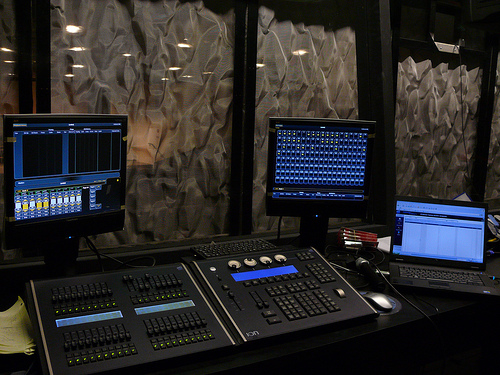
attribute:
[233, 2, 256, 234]
jamb — black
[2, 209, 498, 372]
desk — black, long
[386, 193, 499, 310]
laptop — running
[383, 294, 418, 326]
desk — wooden, black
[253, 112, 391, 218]
screen — blue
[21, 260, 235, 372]
board — mixing, black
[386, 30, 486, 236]
window — large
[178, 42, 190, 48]
reflection — light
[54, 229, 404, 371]
board. — sound board, advanced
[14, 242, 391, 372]
equipment — ready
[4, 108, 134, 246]
screen — blue black and yellow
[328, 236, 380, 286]
microphone — black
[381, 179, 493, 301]
laptop — black